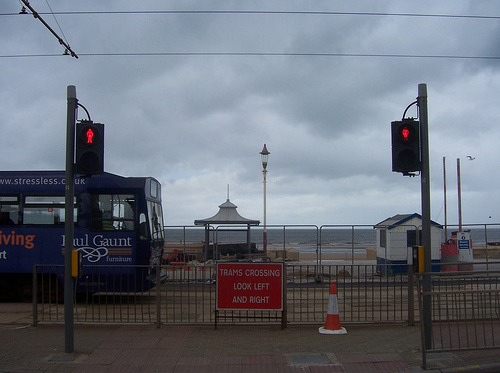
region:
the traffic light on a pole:
[373, 109, 427, 176]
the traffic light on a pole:
[63, 91, 128, 192]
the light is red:
[62, 89, 106, 174]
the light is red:
[383, 115, 427, 187]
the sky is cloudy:
[141, 17, 282, 97]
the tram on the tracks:
[4, 155, 181, 293]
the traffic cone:
[310, 275, 360, 336]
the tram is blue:
[1, 153, 185, 295]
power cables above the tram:
[19, 4, 364, 75]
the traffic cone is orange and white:
[296, 274, 354, 338]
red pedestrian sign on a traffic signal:
[81, 127, 99, 147]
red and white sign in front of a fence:
[216, 263, 283, 311]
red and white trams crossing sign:
[216, 263, 285, 310]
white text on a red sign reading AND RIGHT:
[228, 290, 276, 306]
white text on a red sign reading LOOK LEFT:
[228, 279, 274, 291]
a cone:
[317, 278, 353, 338]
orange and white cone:
[317, 279, 350, 337]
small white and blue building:
[370, 210, 447, 274]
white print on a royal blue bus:
[0, 174, 67, 185]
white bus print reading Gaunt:
[93, 233, 132, 248]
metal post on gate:
[192, 270, 202, 325]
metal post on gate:
[283, 266, 300, 323]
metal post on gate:
[350, 270, 363, 325]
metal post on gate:
[428, 294, 448, 351]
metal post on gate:
[448, 297, 463, 348]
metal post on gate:
[189, 265, 199, 319]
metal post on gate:
[100, 267, 110, 321]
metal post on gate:
[159, 267, 171, 317]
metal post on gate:
[148, 263, 166, 329]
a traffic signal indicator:
[63, 114, 115, 194]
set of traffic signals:
[32, 85, 498, 261]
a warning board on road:
[305, 280, 362, 369]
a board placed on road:
[198, 245, 312, 340]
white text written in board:
[223, 268, 278, 303]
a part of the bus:
[24, 172, 214, 319]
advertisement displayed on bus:
[6, 226, 142, 277]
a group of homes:
[168, 182, 487, 283]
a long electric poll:
[252, 133, 289, 288]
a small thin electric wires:
[16, 13, 497, 113]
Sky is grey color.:
[122, 88, 351, 133]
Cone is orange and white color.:
[316, 276, 350, 350]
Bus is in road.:
[10, 162, 167, 292]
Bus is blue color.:
[8, 163, 168, 297]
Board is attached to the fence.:
[201, 261, 302, 320]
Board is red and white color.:
[213, 257, 292, 326]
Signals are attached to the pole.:
[66, 103, 458, 208]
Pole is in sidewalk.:
[41, 88, 443, 362]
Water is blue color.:
[178, 208, 362, 248]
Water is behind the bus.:
[156, 213, 399, 250]